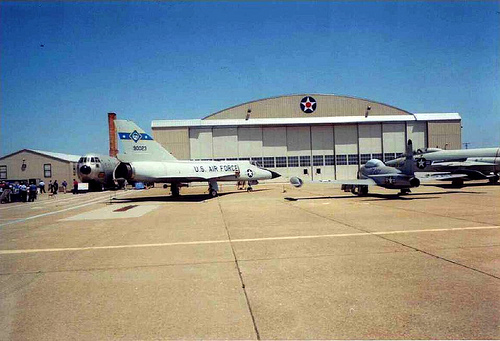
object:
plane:
[109, 117, 283, 203]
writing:
[220, 164, 239, 171]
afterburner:
[111, 160, 136, 184]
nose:
[268, 169, 283, 180]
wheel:
[208, 188, 217, 197]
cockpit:
[250, 160, 268, 175]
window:
[299, 155, 310, 168]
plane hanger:
[150, 90, 465, 189]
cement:
[248, 208, 488, 338]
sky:
[0, 0, 482, 85]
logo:
[299, 94, 318, 115]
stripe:
[117, 131, 154, 141]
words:
[207, 164, 220, 173]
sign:
[119, 128, 147, 143]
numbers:
[132, 145, 137, 151]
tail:
[111, 119, 174, 163]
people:
[70, 177, 79, 194]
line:
[35, 231, 360, 254]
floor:
[0, 204, 500, 341]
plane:
[314, 139, 500, 197]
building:
[150, 91, 468, 182]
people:
[60, 179, 69, 195]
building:
[0, 147, 87, 192]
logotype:
[246, 169, 254, 179]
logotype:
[416, 157, 428, 170]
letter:
[223, 164, 228, 171]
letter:
[213, 165, 219, 173]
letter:
[219, 164, 224, 172]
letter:
[208, 165, 214, 172]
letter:
[200, 166, 206, 173]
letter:
[193, 165, 200, 173]